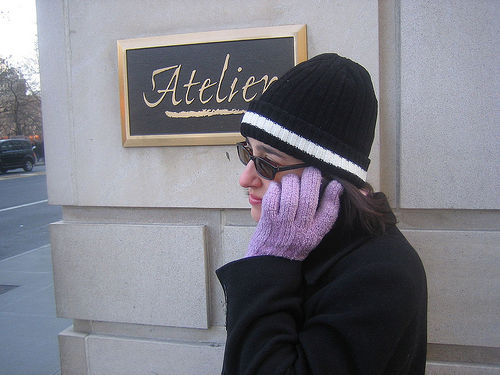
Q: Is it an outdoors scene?
A: Yes, it is outdoors.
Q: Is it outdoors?
A: Yes, it is outdoors.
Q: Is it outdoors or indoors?
A: It is outdoors.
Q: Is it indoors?
A: No, it is outdoors.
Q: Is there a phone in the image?
A: Yes, there is a phone.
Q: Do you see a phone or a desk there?
A: Yes, there is a phone.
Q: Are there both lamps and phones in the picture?
A: No, there is a phone but no lamps.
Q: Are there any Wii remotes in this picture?
A: No, there are no Wii remotes.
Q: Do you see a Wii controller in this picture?
A: No, there are no Wii controllers.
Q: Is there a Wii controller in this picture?
A: No, there are no Wii controllers.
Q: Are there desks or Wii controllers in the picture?
A: No, there are no Wii controllers or desks.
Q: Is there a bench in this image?
A: No, there are no benches.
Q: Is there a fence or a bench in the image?
A: No, there are no benches or fences.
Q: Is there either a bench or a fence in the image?
A: No, there are no benches or fences.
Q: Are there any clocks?
A: No, there are no clocks.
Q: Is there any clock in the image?
A: No, there are no clocks.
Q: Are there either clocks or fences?
A: No, there are no clocks or fences.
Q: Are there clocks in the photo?
A: No, there are no clocks.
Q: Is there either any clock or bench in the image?
A: No, there are no clocks or benches.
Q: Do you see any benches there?
A: No, there are no benches.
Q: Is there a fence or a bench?
A: No, there are no benches or fences.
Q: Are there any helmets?
A: No, there are no helmets.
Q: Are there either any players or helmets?
A: No, there are no helmets or players.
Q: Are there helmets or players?
A: No, there are no helmets or players.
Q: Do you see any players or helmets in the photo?
A: No, there are no helmets or players.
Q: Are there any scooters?
A: No, there are no scooters.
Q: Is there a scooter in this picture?
A: No, there are no scooters.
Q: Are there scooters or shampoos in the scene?
A: No, there are no scooters or shampoos.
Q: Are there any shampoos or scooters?
A: No, there are no scooters or shampoos.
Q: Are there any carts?
A: No, there are no carts.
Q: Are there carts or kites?
A: No, there are no carts or kites.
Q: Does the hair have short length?
A: Yes, the hair is short.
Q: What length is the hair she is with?
A: The hair is short.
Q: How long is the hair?
A: The hair is short.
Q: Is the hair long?
A: No, the hair is short.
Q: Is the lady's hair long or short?
A: The hair is short.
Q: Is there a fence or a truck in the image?
A: No, there are no fences or trucks.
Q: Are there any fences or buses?
A: No, there are no fences or buses.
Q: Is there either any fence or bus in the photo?
A: No, there are no fences or buses.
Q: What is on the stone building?
A: The sign is on the building.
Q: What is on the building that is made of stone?
A: The sign is on the building.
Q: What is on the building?
A: The sign is on the building.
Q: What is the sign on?
A: The sign is on the building.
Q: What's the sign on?
A: The sign is on the building.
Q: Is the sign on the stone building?
A: Yes, the sign is on the building.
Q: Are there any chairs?
A: No, there are no chairs.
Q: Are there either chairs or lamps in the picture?
A: No, there are no chairs or lamps.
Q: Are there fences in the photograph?
A: No, there are no fences.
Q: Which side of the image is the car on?
A: The car is on the left of the image.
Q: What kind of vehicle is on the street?
A: The vehicle is a car.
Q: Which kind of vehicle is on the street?
A: The vehicle is a car.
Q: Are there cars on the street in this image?
A: Yes, there is a car on the street.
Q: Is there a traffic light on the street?
A: No, there is a car on the street.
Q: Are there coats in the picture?
A: Yes, there is a coat.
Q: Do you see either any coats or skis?
A: Yes, there is a coat.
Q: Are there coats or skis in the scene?
A: Yes, there is a coat.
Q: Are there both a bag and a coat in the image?
A: No, there is a coat but no bags.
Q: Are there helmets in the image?
A: No, there are no helmets.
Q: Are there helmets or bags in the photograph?
A: No, there are no helmets or bags.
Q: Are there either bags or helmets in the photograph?
A: No, there are no helmets or bags.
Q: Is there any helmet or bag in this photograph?
A: No, there are no helmets or bags.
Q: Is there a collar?
A: Yes, there is a collar.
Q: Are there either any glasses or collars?
A: Yes, there is a collar.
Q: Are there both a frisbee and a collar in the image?
A: No, there is a collar but no frisbees.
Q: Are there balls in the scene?
A: No, there are no balls.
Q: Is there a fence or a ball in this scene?
A: No, there are no balls or fences.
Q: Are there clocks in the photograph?
A: No, there are no clocks.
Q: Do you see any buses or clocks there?
A: No, there are no clocks or buses.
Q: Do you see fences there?
A: No, there are no fences.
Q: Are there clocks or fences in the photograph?
A: No, there are no fences or clocks.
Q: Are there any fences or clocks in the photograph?
A: No, there are no fences or clocks.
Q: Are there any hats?
A: Yes, there is a hat.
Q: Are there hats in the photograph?
A: Yes, there is a hat.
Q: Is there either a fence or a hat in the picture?
A: Yes, there is a hat.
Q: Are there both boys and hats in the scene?
A: No, there is a hat but no boys.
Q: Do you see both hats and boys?
A: No, there is a hat but no boys.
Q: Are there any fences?
A: No, there are no fences.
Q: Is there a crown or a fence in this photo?
A: No, there are no fences or crowns.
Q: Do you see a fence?
A: No, there are no fences.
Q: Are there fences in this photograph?
A: No, there are no fences.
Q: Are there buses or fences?
A: No, there are no fences or buses.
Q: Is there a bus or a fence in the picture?
A: No, there are no fences or buses.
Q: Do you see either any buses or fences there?
A: No, there are no fences or buses.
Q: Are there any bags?
A: No, there are no bags.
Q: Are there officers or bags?
A: No, there are no bags or officers.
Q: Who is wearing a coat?
A: The lady is wearing a coat.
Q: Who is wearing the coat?
A: The lady is wearing a coat.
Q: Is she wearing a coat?
A: Yes, the lady is wearing a coat.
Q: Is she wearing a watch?
A: No, the lady is wearing a coat.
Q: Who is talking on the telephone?
A: The lady is talking on the telephone.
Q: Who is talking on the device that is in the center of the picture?
A: The lady is talking on the telephone.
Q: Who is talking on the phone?
A: The lady is talking on the telephone.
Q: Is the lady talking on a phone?
A: Yes, the lady is talking on a phone.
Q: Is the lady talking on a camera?
A: No, the lady is talking on a phone.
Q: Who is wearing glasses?
A: The lady is wearing glasses.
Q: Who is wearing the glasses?
A: The lady is wearing glasses.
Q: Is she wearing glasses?
A: Yes, the lady is wearing glasses.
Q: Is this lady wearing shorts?
A: No, the lady is wearing glasses.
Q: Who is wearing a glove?
A: The lady is wearing a glove.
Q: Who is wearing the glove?
A: The lady is wearing a glove.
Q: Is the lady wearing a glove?
A: Yes, the lady is wearing a glove.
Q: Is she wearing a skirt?
A: No, the lady is wearing a glove.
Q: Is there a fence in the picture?
A: No, there are no fences.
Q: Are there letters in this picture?
A: Yes, there are letters.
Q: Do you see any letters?
A: Yes, there are letters.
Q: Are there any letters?
A: Yes, there are letters.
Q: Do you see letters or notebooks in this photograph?
A: Yes, there are letters.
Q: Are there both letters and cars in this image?
A: Yes, there are both letters and a car.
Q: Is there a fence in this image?
A: No, there are no fences.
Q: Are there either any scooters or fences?
A: No, there are no fences or scooters.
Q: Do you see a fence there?
A: No, there are no fences.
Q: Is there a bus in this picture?
A: No, there are no buses.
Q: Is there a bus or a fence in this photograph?
A: No, there are no buses or fences.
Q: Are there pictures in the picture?
A: No, there are no pictures.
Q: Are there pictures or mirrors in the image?
A: No, there are no pictures or mirrors.